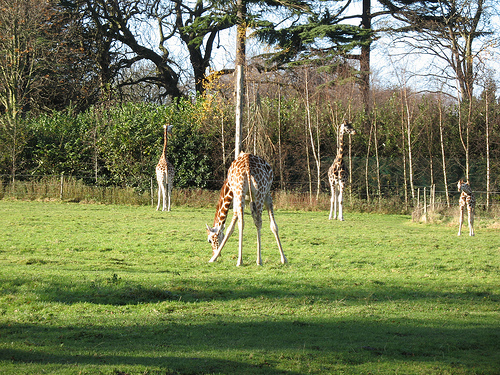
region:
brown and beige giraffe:
[195, 142, 305, 297]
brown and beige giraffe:
[141, 105, 181, 210]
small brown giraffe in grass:
[443, 156, 489, 249]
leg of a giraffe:
[231, 216, 249, 276]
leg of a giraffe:
[250, 211, 265, 276]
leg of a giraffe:
[265, 201, 287, 271]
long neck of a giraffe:
[150, 132, 177, 160]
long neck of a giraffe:
[321, 140, 354, 160]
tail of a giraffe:
[241, 173, 261, 223]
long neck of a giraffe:
[207, 190, 231, 226]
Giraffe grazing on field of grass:
[204, 150, 288, 268]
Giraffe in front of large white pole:
[203, 148, 288, 267]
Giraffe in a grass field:
[155, 121, 175, 213]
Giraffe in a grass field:
[325, 119, 357, 221]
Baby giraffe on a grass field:
[455, 178, 478, 240]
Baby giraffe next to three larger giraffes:
[454, 178, 470, 237]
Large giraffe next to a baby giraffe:
[327, 117, 356, 221]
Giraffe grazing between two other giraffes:
[204, 149, 292, 270]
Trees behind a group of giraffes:
[51, 69, 472, 215]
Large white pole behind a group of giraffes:
[234, 5, 246, 158]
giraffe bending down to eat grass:
[203, 150, 294, 273]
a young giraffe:
[447, 175, 477, 240]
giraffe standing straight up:
[151, 118, 178, 212]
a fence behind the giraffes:
[2, 168, 498, 225]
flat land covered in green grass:
[0, 195, 496, 372]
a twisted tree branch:
[100, 0, 198, 110]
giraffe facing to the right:
[325, 117, 360, 227]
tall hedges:
[26, 92, 221, 192]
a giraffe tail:
[241, 170, 259, 221]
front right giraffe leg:
[265, 199, 290, 267]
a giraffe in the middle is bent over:
[209, 150, 281, 273]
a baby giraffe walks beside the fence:
[448, 174, 479, 236]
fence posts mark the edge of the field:
[404, 186, 454, 231]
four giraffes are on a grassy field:
[147, 195, 497, 269]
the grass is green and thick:
[8, 203, 498, 352]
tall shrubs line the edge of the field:
[26, 100, 494, 183]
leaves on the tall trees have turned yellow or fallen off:
[3, 3, 497, 128]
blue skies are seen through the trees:
[124, 2, 492, 94]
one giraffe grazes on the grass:
[204, 151, 284, 268]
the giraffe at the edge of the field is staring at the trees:
[148, 118, 180, 216]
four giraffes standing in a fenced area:
[152, 120, 473, 265]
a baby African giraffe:
[451, 175, 471, 230]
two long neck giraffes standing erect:
[151, 116, 356, 216]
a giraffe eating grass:
[205, 150, 290, 265]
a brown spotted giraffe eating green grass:
[202, 150, 287, 265]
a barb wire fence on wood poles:
[0, 170, 490, 205]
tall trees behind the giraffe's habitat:
[0, 0, 495, 195]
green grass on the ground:
[0, 270, 495, 370]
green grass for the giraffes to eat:
[1, 267, 492, 372]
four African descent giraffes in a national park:
[152, 118, 477, 266]